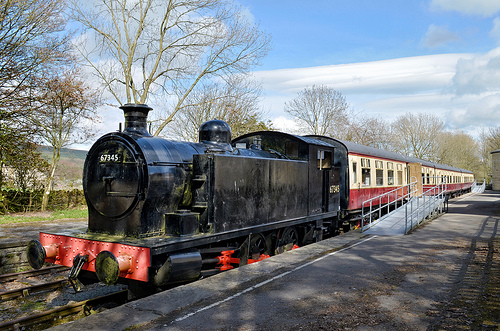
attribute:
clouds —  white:
[262, 39, 499, 122]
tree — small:
[34, 68, 91, 210]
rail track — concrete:
[0, 226, 147, 325]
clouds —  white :
[255, 52, 493, 99]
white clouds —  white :
[218, 52, 498, 99]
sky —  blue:
[1, 0, 499, 151]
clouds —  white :
[0, 1, 499, 150]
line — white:
[224, 285, 251, 301]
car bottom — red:
[347, 185, 417, 208]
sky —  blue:
[275, 5, 496, 80]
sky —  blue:
[259, 2, 493, 89]